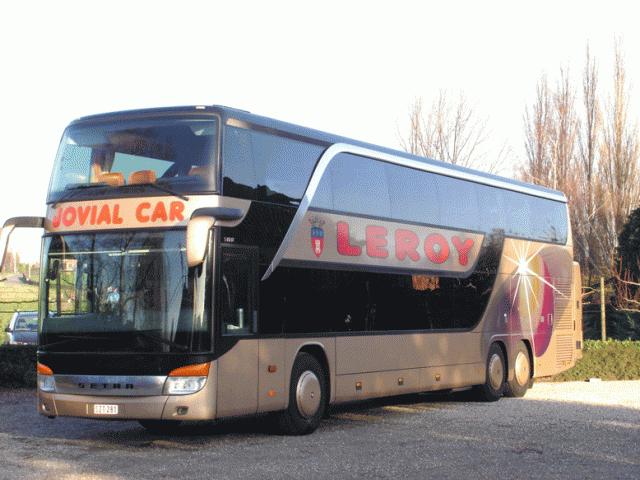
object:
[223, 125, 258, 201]
window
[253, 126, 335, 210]
window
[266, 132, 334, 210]
window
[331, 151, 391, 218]
window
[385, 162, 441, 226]
window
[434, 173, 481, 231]
window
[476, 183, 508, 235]
window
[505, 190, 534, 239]
window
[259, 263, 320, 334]
window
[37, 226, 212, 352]
window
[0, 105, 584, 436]
bus